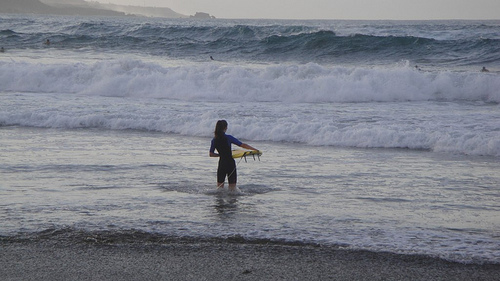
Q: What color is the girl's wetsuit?
A: Blue and black.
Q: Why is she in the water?
A: To surf.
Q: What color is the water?
A: Blue and white.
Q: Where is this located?
A: At the beach.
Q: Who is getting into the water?
A: The girl.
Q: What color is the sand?
A: Grey.